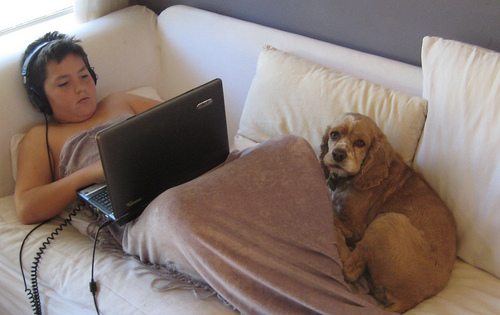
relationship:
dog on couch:
[320, 113, 457, 314] [6, 6, 498, 314]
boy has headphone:
[16, 34, 164, 226] [22, 34, 98, 114]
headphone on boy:
[22, 34, 98, 114] [16, 34, 164, 226]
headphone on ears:
[22, 34, 98, 114] [27, 69, 98, 114]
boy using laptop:
[16, 34, 164, 226] [78, 78, 234, 225]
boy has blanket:
[16, 34, 164, 226] [63, 113, 374, 313]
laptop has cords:
[78, 78, 234, 225] [20, 200, 112, 313]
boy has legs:
[16, 34, 164, 226] [157, 137, 374, 313]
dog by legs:
[320, 113, 457, 314] [157, 137, 374, 313]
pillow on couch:
[236, 47, 431, 163] [6, 6, 498, 314]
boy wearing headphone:
[16, 34, 164, 226] [22, 34, 98, 114]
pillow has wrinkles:
[236, 47, 431, 163] [311, 65, 397, 127]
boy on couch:
[16, 34, 164, 226] [6, 6, 498, 314]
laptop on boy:
[78, 78, 234, 225] [16, 34, 164, 226]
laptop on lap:
[78, 78, 234, 225] [112, 152, 242, 265]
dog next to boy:
[320, 113, 457, 314] [16, 34, 164, 226]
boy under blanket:
[16, 34, 164, 226] [63, 113, 374, 313]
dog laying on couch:
[320, 113, 457, 314] [6, 6, 498, 314]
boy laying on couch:
[16, 34, 164, 226] [6, 6, 498, 314]